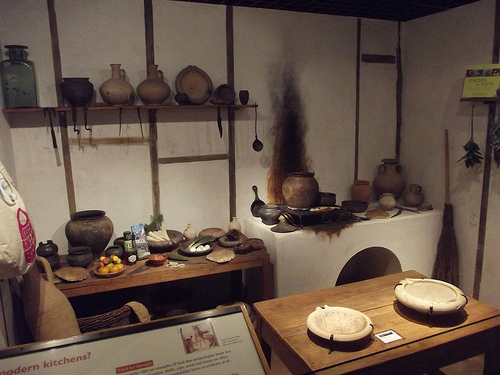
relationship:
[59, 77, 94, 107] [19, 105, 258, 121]
antiquity on shelf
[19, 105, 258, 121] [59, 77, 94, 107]
shelf has antiquity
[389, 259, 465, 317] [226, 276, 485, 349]
pie on table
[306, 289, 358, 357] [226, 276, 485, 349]
pie on table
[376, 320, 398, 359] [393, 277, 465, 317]
sticker between pie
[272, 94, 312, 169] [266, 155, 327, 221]
stain behind pot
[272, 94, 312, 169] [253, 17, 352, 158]
stain on wall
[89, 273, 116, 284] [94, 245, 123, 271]
plate has items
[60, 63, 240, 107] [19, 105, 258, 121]
jars on shelf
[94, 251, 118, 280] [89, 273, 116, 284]
vegetables on plate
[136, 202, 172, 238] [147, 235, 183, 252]
parsnips on bowl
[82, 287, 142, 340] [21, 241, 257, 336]
basket under table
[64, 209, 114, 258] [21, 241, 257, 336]
antiquity on table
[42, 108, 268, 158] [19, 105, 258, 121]
utensils hang from shelf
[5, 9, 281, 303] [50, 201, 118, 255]
display of antiquity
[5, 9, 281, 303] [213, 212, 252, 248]
display of antiquity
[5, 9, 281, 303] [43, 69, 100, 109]
display of antiquity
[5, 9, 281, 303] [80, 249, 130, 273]
display of antiquity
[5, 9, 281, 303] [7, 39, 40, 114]
display of antiquity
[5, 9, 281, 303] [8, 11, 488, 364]
display in museum